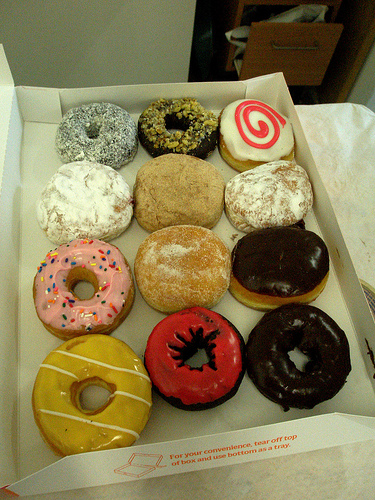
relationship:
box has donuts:
[3, 69, 374, 490] [30, 96, 353, 458]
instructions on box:
[147, 425, 328, 476] [3, 69, 374, 490]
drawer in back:
[241, 2, 335, 86] [2, 2, 372, 74]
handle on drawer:
[268, 39, 325, 53] [241, 2, 335, 86]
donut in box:
[236, 298, 362, 413] [3, 69, 374, 490]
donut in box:
[27, 238, 137, 335] [3, 69, 374, 490]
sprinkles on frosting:
[36, 239, 125, 326] [31, 240, 137, 332]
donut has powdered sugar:
[35, 159, 137, 241] [40, 159, 133, 242]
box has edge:
[3, 69, 374, 490] [5, 72, 298, 96]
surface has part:
[5, 0, 192, 83] [50, 20, 134, 63]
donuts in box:
[30, 96, 353, 458] [3, 69, 374, 490]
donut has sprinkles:
[27, 238, 137, 335] [36, 239, 125, 326]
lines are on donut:
[25, 347, 153, 443] [24, 338, 150, 455]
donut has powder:
[228, 160, 316, 225] [230, 164, 317, 229]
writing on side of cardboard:
[147, 425, 328, 476] [3, 414, 374, 496]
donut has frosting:
[236, 298, 362, 413] [243, 303, 354, 408]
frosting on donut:
[243, 303, 354, 408] [236, 298, 362, 413]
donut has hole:
[236, 298, 362, 413] [274, 333, 327, 383]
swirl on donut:
[228, 98, 290, 150] [219, 96, 299, 165]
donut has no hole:
[35, 159, 137, 241] [67, 177, 106, 217]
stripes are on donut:
[25, 347, 153, 443] [24, 338, 150, 455]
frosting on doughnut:
[31, 240, 137, 332] [27, 238, 137, 335]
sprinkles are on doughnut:
[36, 239, 125, 326] [27, 238, 137, 335]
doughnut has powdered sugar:
[35, 159, 137, 241] [40, 159, 133, 242]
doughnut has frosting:
[219, 96, 299, 165] [219, 98, 298, 164]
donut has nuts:
[141, 95, 218, 158] [140, 99, 217, 154]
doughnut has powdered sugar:
[53, 102, 139, 165] [55, 107, 139, 160]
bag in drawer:
[230, 6, 334, 68] [241, 2, 335, 86]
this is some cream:
[144, 308, 251, 414] [144, 305, 243, 405]